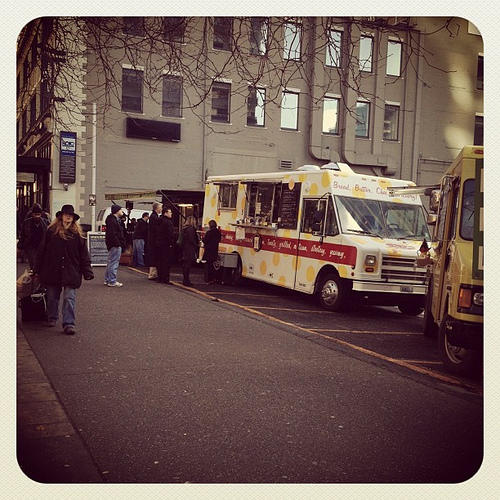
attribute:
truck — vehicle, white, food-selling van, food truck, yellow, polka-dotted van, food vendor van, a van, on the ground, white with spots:
[201, 163, 429, 315]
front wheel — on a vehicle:
[311, 277, 343, 311]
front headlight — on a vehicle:
[364, 250, 378, 270]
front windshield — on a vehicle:
[333, 192, 421, 243]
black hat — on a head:
[54, 203, 77, 218]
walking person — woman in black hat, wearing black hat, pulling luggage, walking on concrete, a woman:
[37, 205, 92, 337]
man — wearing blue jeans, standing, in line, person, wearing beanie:
[107, 206, 128, 290]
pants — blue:
[108, 250, 122, 283]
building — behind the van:
[16, 17, 480, 243]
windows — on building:
[112, 64, 405, 141]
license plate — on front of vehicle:
[402, 286, 415, 298]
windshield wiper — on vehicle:
[348, 228, 384, 238]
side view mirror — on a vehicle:
[314, 206, 326, 235]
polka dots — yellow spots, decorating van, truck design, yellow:
[255, 253, 289, 283]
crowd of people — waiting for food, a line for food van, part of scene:
[105, 189, 219, 287]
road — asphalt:
[59, 264, 493, 485]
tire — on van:
[400, 305, 421, 314]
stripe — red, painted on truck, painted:
[221, 224, 352, 266]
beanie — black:
[110, 206, 120, 216]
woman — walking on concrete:
[21, 206, 46, 268]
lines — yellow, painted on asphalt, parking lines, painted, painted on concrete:
[234, 286, 449, 381]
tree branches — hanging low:
[63, 18, 465, 97]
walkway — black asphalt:
[17, 263, 429, 481]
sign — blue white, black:
[57, 132, 80, 185]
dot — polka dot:
[307, 178, 319, 197]